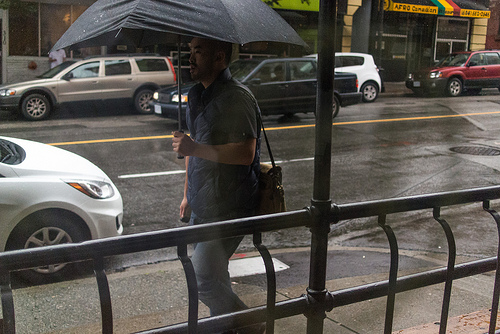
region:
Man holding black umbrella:
[174, 43, 266, 323]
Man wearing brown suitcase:
[165, 40, 266, 332]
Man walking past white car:
[172, 38, 265, 328]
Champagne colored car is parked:
[0, 56, 178, 121]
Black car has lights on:
[145, 56, 366, 119]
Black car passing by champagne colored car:
[137, 50, 363, 120]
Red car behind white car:
[402, 45, 498, 93]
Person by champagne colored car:
[48, 42, 65, 68]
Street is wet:
[0, 93, 499, 260]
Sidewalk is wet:
[0, 256, 467, 332]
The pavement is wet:
[341, 95, 477, 252]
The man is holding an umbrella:
[61, 32, 340, 271]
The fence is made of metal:
[302, 188, 487, 332]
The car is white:
[3, 125, 151, 267]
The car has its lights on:
[146, 87, 234, 146]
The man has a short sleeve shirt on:
[179, 110, 334, 233]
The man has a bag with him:
[233, 125, 303, 212]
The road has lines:
[343, 84, 497, 200]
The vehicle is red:
[395, 43, 497, 95]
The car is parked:
[1, 49, 201, 134]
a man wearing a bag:
[102, 30, 328, 257]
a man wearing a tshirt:
[134, 45, 291, 248]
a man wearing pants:
[143, 30, 271, 314]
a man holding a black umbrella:
[50, 0, 323, 208]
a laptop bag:
[228, 110, 324, 254]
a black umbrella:
[60, 0, 337, 103]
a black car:
[124, 35, 414, 122]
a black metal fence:
[4, 190, 497, 332]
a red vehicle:
[401, 33, 496, 109]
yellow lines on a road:
[6, 108, 491, 174]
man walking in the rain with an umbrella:
[75, 7, 307, 327]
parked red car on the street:
[406, 45, 496, 93]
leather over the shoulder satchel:
[226, 81, 294, 227]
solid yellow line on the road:
[351, 106, 499, 128]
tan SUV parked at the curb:
[2, 52, 170, 112]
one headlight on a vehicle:
[65, 173, 120, 202]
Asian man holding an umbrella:
[183, 33, 247, 102]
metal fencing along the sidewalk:
[301, 183, 493, 310]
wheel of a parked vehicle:
[18, 89, 55, 120]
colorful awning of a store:
[383, 1, 493, 29]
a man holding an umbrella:
[36, 2, 335, 332]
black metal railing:
[12, 174, 497, 329]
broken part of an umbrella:
[95, 13, 157, 53]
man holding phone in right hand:
[172, 189, 197, 231]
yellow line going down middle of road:
[22, 106, 482, 161]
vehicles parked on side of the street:
[7, 32, 497, 124]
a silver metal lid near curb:
[215, 248, 291, 291]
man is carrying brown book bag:
[141, 27, 296, 232]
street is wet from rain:
[9, 77, 499, 247]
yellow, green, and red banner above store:
[378, 3, 497, 34]